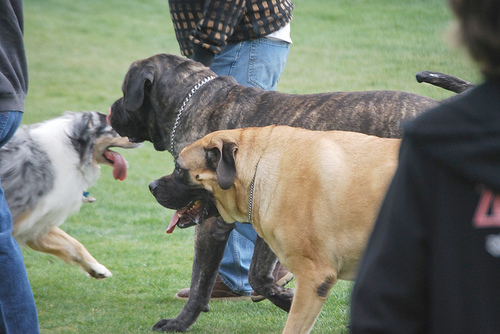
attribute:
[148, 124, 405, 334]
dog — beige, mastiff, playing, tan, walking, golden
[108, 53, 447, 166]
dog — black, brown, playing, chocolate, walking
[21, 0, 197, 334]
grass — green, manicured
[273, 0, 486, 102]
grass — green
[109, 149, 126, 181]
tounge — large, out, pink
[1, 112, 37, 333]
jeans — blue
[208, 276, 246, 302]
shoe — brown, borwn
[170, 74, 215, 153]
chain — silver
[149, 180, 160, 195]
nose — black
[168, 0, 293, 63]
sweater — checkered, plaid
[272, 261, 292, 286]
shoe — borwn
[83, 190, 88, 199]
tag — blue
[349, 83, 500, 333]
hoodie — black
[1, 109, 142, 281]
dog — collie, playing, walking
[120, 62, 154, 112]
ear — black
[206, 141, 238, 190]
ear — black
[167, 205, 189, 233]
tounge — out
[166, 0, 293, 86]
man — standing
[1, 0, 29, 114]
sweater — gray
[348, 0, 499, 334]
person — standing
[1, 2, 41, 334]
person — standing